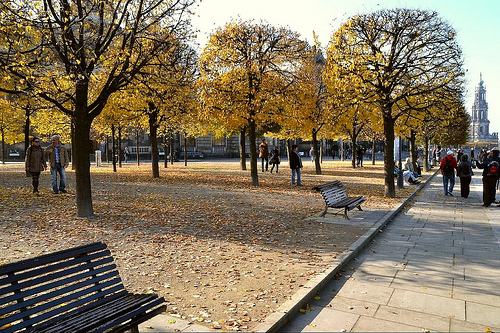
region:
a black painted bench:
[47, 231, 165, 327]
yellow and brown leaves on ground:
[122, 174, 302, 330]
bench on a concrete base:
[260, 168, 382, 285]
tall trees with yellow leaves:
[68, 101, 385, 196]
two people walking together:
[2, 122, 74, 211]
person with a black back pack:
[405, 143, 463, 229]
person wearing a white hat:
[428, 139, 462, 170]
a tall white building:
[455, 102, 497, 154]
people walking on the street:
[366, 138, 484, 263]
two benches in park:
[6, 170, 374, 330]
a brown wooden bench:
[312, 175, 364, 213]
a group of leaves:
[208, 317, 247, 331]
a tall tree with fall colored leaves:
[317, 7, 471, 197]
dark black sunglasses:
[32, 137, 41, 143]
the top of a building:
[470, 70, 492, 139]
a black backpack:
[440, 155, 457, 176]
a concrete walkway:
[275, 172, 498, 332]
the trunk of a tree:
[145, 112, 169, 179]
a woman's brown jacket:
[21, 145, 47, 174]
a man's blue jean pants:
[51, 164, 68, 191]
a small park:
[0, 0, 480, 331]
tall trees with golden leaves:
[1, 0, 479, 219]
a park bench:
[311, 177, 364, 222]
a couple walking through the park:
[23, 131, 70, 196]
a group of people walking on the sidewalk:
[436, 148, 498, 213]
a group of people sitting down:
[388, 151, 430, 192]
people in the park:
[6, 126, 428, 205]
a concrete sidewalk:
[264, 159, 498, 330]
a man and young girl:
[254, 134, 284, 173]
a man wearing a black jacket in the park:
[285, 142, 307, 184]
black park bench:
[311, 177, 368, 217]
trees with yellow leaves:
[0, 3, 472, 215]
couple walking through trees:
[21, 130, 72, 192]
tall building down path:
[464, 70, 492, 140]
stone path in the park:
[281, 158, 498, 330]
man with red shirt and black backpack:
[438, 150, 458, 193]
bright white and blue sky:
[153, 2, 498, 124]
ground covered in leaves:
[6, 157, 420, 325]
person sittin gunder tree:
[397, 165, 424, 185]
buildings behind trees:
[102, 111, 279, 154]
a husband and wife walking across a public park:
[23, 132, 70, 195]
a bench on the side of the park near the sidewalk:
[303, 179, 370, 229]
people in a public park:
[1, 132, 424, 331]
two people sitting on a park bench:
[390, 157, 423, 184]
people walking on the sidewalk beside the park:
[437, 145, 499, 207]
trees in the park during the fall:
[0, 1, 467, 217]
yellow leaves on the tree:
[194, 17, 322, 137]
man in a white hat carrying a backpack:
[438, 148, 458, 198]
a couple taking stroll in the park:
[22, 133, 69, 195]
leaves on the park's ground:
[125, 193, 297, 283]